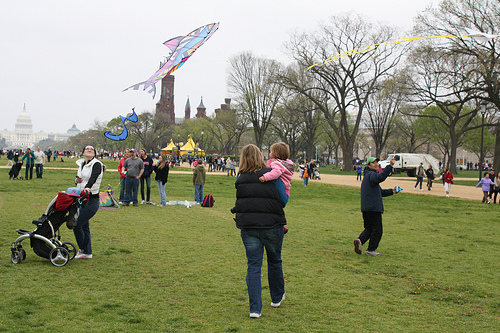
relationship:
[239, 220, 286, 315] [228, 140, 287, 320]
jeans of woman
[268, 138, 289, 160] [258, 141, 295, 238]
hair on baby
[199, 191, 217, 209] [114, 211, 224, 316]
backpack on grass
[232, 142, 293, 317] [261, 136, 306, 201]
woman carrying baby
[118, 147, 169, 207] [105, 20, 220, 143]
people watching kites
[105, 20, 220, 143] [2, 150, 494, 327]
kites fly in park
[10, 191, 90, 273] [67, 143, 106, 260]
black stroller handled by lady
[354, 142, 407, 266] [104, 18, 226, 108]
man flying a kite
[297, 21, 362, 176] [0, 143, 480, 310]
bare tree in park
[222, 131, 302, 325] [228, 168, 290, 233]
woman wearing vest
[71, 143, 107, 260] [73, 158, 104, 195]
lady wearing white vest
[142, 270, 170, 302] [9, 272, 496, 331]
small patch of grass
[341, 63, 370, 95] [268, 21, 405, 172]
branches on bare tree